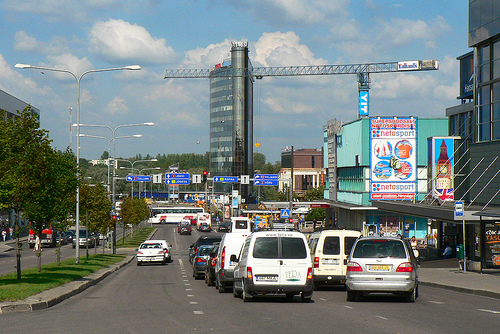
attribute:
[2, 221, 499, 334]
street — busy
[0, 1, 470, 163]
sky — blue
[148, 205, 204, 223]
bus — white, crossing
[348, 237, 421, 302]
van — grey, silver, white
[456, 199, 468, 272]
sign — a bus stop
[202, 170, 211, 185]
traffic light — red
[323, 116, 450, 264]
building — green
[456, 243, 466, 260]
trash — green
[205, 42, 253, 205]
building — tall, glass, metal, blue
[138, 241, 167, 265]
car — white, silver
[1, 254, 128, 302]
grass — green, growing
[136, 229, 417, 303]
cars — stopped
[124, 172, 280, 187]
signs — blue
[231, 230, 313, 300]
van — white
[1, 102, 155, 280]
trees — green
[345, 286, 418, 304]
wheels — black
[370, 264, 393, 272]
license plate — yellow